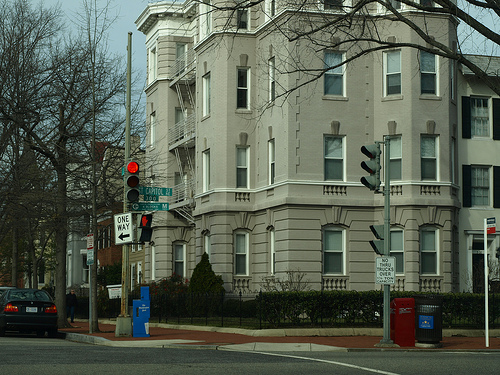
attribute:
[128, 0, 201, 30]
design — white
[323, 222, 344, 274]
window — rectangular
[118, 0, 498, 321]
building — gray, beautiful 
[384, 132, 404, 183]
window — rectangular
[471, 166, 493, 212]
window —  rectangular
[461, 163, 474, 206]
shutter — black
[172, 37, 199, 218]
staircases — outdoor, metal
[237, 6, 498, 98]
branches — surving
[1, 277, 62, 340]
car — dark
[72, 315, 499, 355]
sidewalk — brick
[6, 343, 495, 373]
street — dark gray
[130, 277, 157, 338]
box — blue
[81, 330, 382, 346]
sidewalk — red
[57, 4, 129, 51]
sky — blue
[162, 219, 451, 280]
windows — arched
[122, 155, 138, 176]
signal — red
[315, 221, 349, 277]
window — tall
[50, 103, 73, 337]
tree — tall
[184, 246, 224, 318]
tree — green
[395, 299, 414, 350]
box — NEWSPAPER, RED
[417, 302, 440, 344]
stand — NEWSPAPER, BLACK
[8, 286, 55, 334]
car — BACK, BLUE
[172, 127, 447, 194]
windows — MANY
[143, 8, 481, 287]
house — GRAY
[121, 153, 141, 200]
light — RED, TRAFFIC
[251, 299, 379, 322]
fence — BLACK, IRON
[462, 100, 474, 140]
shutters — BLACK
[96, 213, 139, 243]
sign — BLACK, WHITE, ONE WAY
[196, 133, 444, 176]
windows — LOTS OF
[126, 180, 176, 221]
signs — GREEN, THREE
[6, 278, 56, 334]
car — BLACK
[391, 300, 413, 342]
can — TRASH, RED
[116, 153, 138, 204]
light — RED, STOP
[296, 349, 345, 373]
lines — WHITE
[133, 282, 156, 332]
box — BLUE, PAPER